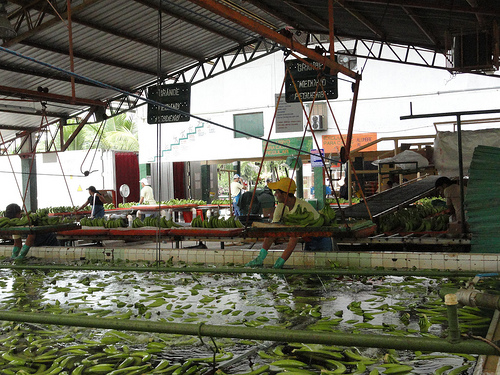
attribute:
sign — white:
[270, 90, 309, 134]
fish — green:
[108, 333, 178, 373]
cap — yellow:
[264, 178, 295, 192]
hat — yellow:
[266, 173, 296, 194]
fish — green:
[319, 284, 388, 333]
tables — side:
[0, 218, 382, 245]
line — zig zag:
[146, 118, 212, 163]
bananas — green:
[4, 245, 499, 374]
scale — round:
[111, 175, 160, 212]